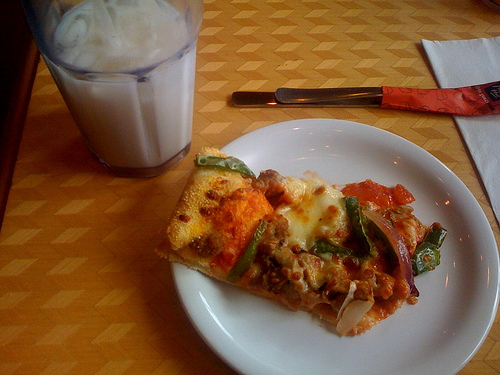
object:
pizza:
[167, 144, 433, 315]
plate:
[171, 117, 494, 375]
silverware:
[228, 69, 496, 126]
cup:
[16, 4, 205, 175]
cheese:
[272, 170, 355, 246]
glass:
[35, 8, 225, 180]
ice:
[55, 24, 164, 71]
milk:
[52, 11, 195, 167]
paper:
[364, 57, 498, 124]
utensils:
[228, 84, 498, 118]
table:
[2, 13, 496, 371]